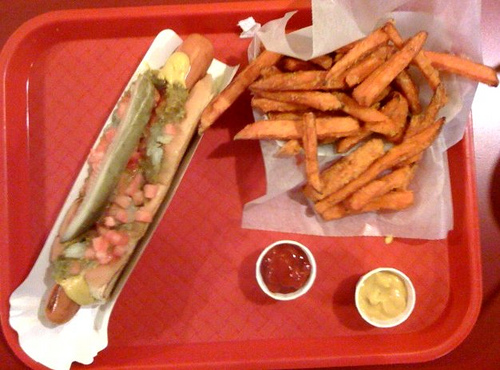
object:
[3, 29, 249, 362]
paper tray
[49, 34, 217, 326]
hotdog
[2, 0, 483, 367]
tray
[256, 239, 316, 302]
cup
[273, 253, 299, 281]
ketchup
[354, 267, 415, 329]
cup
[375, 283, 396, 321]
mustard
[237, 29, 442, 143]
sweet potato fries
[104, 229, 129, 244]
tomatoes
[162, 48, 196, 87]
mustard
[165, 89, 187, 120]
relish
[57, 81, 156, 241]
pickle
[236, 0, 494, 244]
paper tray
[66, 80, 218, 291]
hotdog bun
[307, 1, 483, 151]
parchment paper